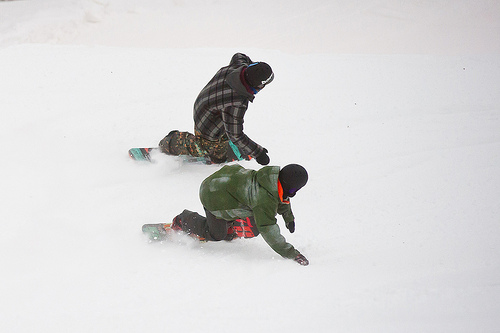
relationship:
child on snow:
[157, 51, 273, 165] [2, 1, 484, 329]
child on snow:
[167, 162, 308, 265] [2, 1, 484, 329]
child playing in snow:
[158, 50, 276, 166] [2, 1, 484, 329]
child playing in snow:
[171, 161, 311, 265] [2, 1, 484, 329]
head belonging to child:
[241, 58, 276, 94] [158, 50, 276, 166]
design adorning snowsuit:
[230, 216, 255, 239] [198, 163, 298, 260]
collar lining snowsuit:
[273, 177, 290, 204] [198, 163, 298, 260]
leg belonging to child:
[171, 204, 229, 243] [167, 162, 308, 265]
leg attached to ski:
[171, 204, 229, 243] [142, 220, 179, 241]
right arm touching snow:
[249, 204, 309, 265] [2, 1, 484, 329]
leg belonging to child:
[155, 128, 223, 164] [157, 51, 273, 165]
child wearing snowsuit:
[157, 51, 273, 165] [191, 54, 264, 163]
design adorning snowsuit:
[228, 137, 245, 161] [191, 54, 264, 163]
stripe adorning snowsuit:
[192, 93, 243, 123] [191, 54, 264, 163]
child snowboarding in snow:
[157, 51, 273, 165] [2, 1, 484, 329]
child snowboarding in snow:
[167, 162, 308, 265] [2, 1, 484, 329]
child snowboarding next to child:
[157, 51, 273, 165] [167, 162, 308, 265]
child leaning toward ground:
[157, 51, 273, 165] [2, 2, 482, 330]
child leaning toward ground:
[167, 162, 308, 265] [2, 2, 482, 330]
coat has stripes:
[190, 52, 264, 160] [205, 90, 229, 129]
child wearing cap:
[167, 162, 308, 265] [271, 157, 316, 210]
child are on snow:
[167, 162, 308, 265] [148, 233, 274, 275]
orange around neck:
[275, 182, 290, 203] [264, 173, 299, 208]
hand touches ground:
[268, 246, 339, 273] [268, 253, 355, 282]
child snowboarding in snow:
[167, 162, 308, 265] [299, 202, 409, 267]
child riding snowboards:
[167, 162, 308, 265] [133, 137, 177, 284]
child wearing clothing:
[167, 162, 308, 265] [197, 161, 300, 260]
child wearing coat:
[157, 51, 273, 165] [179, 54, 266, 150]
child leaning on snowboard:
[167, 162, 308, 265] [129, 203, 299, 259]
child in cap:
[167, 162, 308, 265] [277, 163, 310, 197]